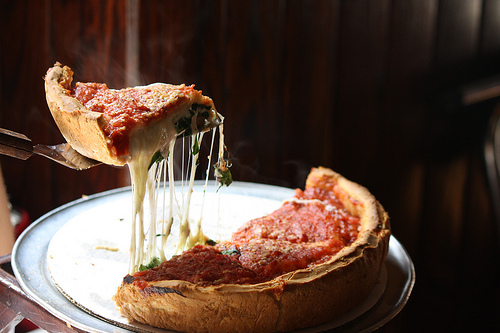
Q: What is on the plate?
A: Pizza.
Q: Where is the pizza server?
A: In the air.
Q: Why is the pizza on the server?
A: To be given to someone.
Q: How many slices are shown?
A: 4.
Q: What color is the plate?
A: White.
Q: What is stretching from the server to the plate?
A: Cheese.